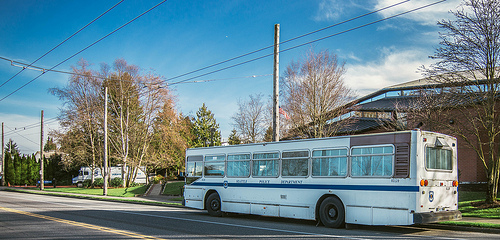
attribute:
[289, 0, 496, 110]
clouds — white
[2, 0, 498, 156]
sky — blue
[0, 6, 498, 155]
clouds — white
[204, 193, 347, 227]
wheels — round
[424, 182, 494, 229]
grass — green, short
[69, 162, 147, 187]
truck — parked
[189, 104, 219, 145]
tree — tall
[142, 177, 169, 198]
walkway — concrete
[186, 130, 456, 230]
bus — white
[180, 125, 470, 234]
bus — blue, white, old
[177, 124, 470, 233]
passenger bus — white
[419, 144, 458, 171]
window — closed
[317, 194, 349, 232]
tire — black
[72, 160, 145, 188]
box truck — white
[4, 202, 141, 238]
line — doubled, yellow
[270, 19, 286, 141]
pole — concrete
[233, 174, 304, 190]
lettering — blue